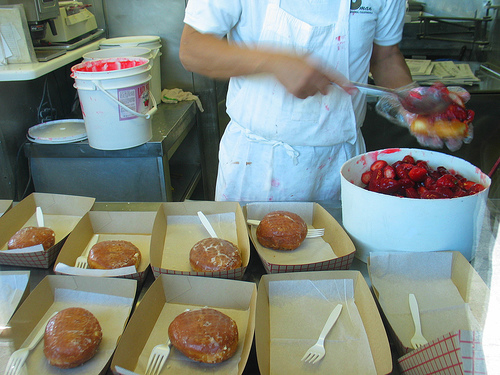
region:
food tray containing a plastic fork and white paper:
[253, 270, 388, 373]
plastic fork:
[299, 299, 349, 366]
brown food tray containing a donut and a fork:
[115, 275, 253, 371]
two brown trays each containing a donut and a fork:
[11, 273, 257, 372]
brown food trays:
[7, 193, 390, 373]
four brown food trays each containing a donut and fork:
[0, 189, 354, 272]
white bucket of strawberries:
[341, 145, 492, 252]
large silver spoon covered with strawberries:
[326, 71, 456, 118]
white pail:
[69, 54, 166, 149]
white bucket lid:
[25, 119, 89, 146]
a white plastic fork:
[299, 297, 347, 364]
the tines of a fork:
[298, 339, 327, 366]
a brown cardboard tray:
[251, 265, 395, 373]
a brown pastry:
[163, 305, 243, 366]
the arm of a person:
[176, 1, 286, 81]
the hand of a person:
[276, 44, 361, 113]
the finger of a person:
[316, 57, 361, 99]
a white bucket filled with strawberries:
[334, 136, 492, 266]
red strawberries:
[345, 143, 487, 205]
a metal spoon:
[323, 75, 453, 122]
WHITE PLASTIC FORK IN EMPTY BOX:
[294, 297, 346, 369]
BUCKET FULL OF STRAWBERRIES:
[339, 142, 489, 270]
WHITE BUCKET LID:
[23, 118, 93, 146]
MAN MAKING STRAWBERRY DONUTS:
[177, 2, 478, 204]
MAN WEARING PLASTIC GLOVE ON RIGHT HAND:
[177, 0, 477, 203]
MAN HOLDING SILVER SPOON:
[177, 1, 479, 200]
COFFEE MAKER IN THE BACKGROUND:
[10, 0, 62, 63]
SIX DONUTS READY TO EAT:
[1, 195, 323, 373]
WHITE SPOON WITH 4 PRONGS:
[295, 300, 343, 366]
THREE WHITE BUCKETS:
[72, 33, 168, 151]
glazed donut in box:
[163, 298, 255, 370]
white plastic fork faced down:
[11, 324, 53, 373]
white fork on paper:
[291, 295, 355, 372]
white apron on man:
[218, 8, 374, 195]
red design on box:
[413, 334, 463, 370]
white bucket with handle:
[69, 55, 164, 160]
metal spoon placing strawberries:
[372, 74, 462, 119]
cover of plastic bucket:
[21, 112, 92, 152]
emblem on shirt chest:
[343, 0, 376, 34]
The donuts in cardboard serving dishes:
[7, 211, 306, 368]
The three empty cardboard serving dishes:
[251, 249, 498, 374]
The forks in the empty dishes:
[296, 290, 429, 365]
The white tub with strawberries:
[331, 140, 494, 271]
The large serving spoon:
[336, 71, 451, 122]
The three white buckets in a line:
[69, 22, 167, 152]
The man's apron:
[217, 0, 367, 217]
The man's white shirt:
[183, 0, 408, 157]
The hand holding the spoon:
[262, 46, 364, 104]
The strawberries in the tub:
[359, 152, 483, 201]